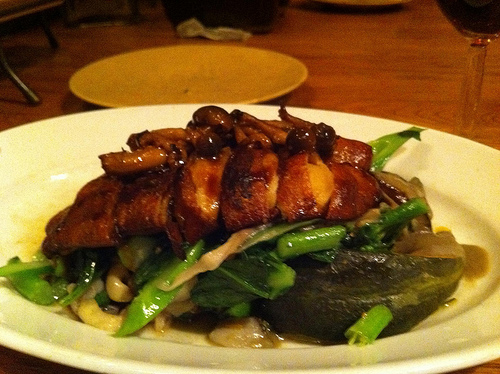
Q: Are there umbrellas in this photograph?
A: No, there are no umbrellas.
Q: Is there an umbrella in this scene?
A: No, there are no umbrellas.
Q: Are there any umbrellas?
A: No, there are no umbrellas.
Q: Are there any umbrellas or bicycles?
A: No, there are no umbrellas or bicycles.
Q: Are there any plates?
A: Yes, there is a plate.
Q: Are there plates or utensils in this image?
A: Yes, there is a plate.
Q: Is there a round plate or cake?
A: Yes, there is a round plate.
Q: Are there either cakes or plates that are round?
A: Yes, the plate is round.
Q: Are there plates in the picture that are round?
A: Yes, there is a round plate.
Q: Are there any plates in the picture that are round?
A: Yes, there is a plate that is round.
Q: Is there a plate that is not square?
A: Yes, there is a round plate.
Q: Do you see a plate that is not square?
A: Yes, there is a round plate.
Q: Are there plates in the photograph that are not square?
A: Yes, there is a round plate.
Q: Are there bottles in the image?
A: No, there are no bottles.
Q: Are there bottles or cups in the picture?
A: No, there are no bottles or cups.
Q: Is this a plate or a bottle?
A: This is a plate.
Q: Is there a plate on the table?
A: Yes, there is a plate on the table.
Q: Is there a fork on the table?
A: No, there is a plate on the table.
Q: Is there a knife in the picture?
A: No, there are no knives.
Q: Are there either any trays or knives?
A: No, there are no knives or trays.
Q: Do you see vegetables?
A: Yes, there are vegetables.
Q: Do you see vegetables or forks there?
A: Yes, there are vegetables.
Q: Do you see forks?
A: No, there are no forks.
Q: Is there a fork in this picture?
A: No, there are no forks.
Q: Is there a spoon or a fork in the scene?
A: No, there are no forks or spoons.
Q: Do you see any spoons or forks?
A: No, there are no forks or spoons.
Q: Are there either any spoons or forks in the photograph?
A: No, there are no forks or spoons.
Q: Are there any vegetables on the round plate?
A: Yes, there are vegetables on the plate.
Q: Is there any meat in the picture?
A: Yes, there is meat.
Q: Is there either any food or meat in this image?
A: Yes, there is meat.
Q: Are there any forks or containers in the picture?
A: No, there are no forks or containers.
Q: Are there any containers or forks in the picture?
A: No, there are no forks or containers.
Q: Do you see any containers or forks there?
A: No, there are no forks or containers.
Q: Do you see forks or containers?
A: No, there are no forks or containers.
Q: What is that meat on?
A: The meat is on the plate.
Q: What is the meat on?
A: The meat is on the plate.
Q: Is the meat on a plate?
A: Yes, the meat is on a plate.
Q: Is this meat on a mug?
A: No, the meat is on a plate.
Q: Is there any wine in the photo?
A: Yes, there is wine.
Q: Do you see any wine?
A: Yes, there is wine.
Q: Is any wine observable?
A: Yes, there is wine.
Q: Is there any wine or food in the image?
A: Yes, there is wine.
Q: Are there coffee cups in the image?
A: No, there are no coffee cups.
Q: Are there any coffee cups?
A: No, there are no coffee cups.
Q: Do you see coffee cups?
A: No, there are no coffee cups.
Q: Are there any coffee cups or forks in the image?
A: No, there are no coffee cups or forks.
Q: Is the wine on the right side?
A: Yes, the wine is on the right of the image.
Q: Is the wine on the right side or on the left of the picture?
A: The wine is on the right of the image.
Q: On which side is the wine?
A: The wine is on the right of the image.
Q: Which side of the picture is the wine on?
A: The wine is on the right of the image.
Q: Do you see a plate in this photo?
A: Yes, there is a plate.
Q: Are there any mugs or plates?
A: Yes, there is a plate.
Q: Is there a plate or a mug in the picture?
A: Yes, there is a plate.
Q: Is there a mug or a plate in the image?
A: Yes, there is a plate.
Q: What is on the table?
A: The plate is on the table.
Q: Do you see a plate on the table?
A: Yes, there is a plate on the table.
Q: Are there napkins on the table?
A: No, there is a plate on the table.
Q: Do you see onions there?
A: Yes, there are onions.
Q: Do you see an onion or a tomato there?
A: Yes, there are onions.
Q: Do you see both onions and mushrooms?
A: Yes, there are both onions and a mushroom.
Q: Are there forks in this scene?
A: No, there are no forks.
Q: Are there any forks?
A: No, there are no forks.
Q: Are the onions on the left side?
A: Yes, the onions are on the left of the image.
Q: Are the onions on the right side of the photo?
A: No, the onions are on the left of the image.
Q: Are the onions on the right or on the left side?
A: The onions are on the left of the image.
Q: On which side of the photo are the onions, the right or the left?
A: The onions are on the left of the image.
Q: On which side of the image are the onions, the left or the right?
A: The onions are on the left of the image.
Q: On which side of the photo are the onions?
A: The onions are on the left of the image.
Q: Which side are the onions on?
A: The onions are on the left of the image.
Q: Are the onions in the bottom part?
A: Yes, the onions are in the bottom of the image.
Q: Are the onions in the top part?
A: No, the onions are in the bottom of the image.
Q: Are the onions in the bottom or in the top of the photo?
A: The onions are in the bottom of the image.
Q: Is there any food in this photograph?
A: Yes, there is food.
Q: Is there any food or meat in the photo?
A: Yes, there is food.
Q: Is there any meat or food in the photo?
A: Yes, there is food.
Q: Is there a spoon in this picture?
A: No, there are no spoons.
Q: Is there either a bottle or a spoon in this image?
A: No, there are no spoons or bottles.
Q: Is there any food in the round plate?
A: Yes, there is food in the plate.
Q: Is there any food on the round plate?
A: Yes, there is food on the plate.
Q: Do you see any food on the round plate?
A: Yes, there is food on the plate.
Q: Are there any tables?
A: Yes, there is a table.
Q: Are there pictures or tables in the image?
A: Yes, there is a table.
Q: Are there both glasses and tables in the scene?
A: Yes, there are both a table and glasses.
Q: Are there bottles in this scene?
A: No, there are no bottles.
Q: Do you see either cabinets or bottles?
A: No, there are no bottles or cabinets.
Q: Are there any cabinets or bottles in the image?
A: No, there are no bottles or cabinets.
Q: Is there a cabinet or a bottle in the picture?
A: No, there are no bottles or cabinets.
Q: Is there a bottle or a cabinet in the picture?
A: No, there are no bottles or cabinets.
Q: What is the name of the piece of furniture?
A: The piece of furniture is a table.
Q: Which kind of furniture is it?
A: The piece of furniture is a table.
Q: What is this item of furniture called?
A: This is a table.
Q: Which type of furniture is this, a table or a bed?
A: This is a table.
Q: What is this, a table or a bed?
A: This is a table.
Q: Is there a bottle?
A: No, there are no bottles.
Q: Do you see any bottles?
A: No, there are no bottles.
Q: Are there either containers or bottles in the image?
A: No, there are no bottles or containers.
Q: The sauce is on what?
A: The sauce is on the plate.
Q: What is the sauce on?
A: The sauce is on the plate.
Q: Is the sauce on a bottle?
A: No, the sauce is on the plate.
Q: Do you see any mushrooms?
A: Yes, there are mushrooms.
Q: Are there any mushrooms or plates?
A: Yes, there are mushrooms.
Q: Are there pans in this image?
A: No, there are no pans.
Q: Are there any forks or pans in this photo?
A: No, there are no pans or forks.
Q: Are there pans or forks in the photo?
A: No, there are no pans or forks.